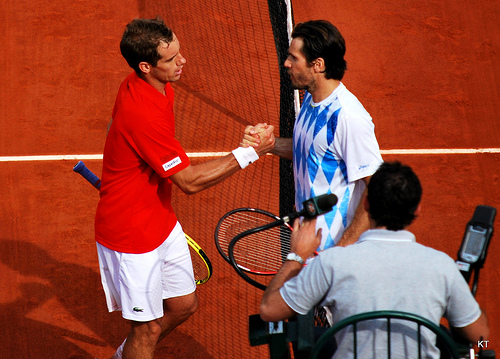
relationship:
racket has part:
[213, 207, 317, 277] [231, 216, 286, 271]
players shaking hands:
[74, 12, 426, 349] [235, 114, 289, 175]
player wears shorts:
[84, 12, 269, 357] [91, 224, 201, 324]